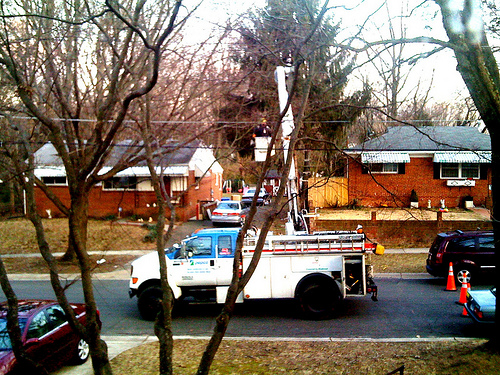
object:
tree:
[210, 0, 374, 211]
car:
[0, 299, 102, 375]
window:
[103, 175, 138, 192]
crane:
[272, 65, 321, 236]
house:
[24, 139, 220, 221]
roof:
[344, 125, 490, 152]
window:
[431, 161, 487, 182]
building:
[335, 125, 496, 212]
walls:
[35, 175, 187, 222]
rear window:
[216, 202, 239, 210]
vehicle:
[210, 200, 251, 227]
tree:
[0, 0, 260, 260]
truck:
[126, 226, 384, 322]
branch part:
[239, 51, 320, 282]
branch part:
[231, 63, 297, 290]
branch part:
[115, 124, 215, 175]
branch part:
[105, 0, 156, 50]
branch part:
[153, 0, 181, 48]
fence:
[312, 199, 493, 244]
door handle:
[210, 260, 215, 267]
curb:
[93, 334, 497, 375]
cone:
[444, 261, 459, 292]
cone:
[455, 273, 469, 305]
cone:
[461, 284, 471, 317]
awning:
[433, 149, 491, 165]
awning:
[360, 150, 410, 164]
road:
[0, 258, 498, 340]